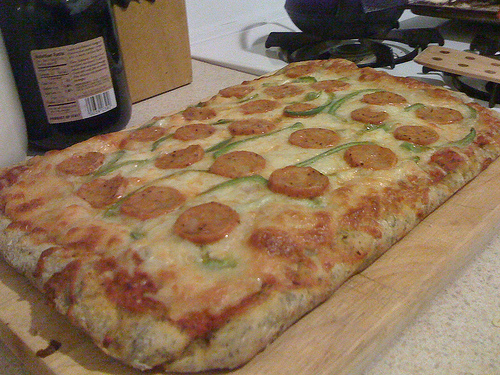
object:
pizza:
[1, 58, 499, 375]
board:
[1, 157, 500, 373]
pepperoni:
[174, 202, 241, 246]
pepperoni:
[266, 164, 332, 199]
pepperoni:
[54, 150, 105, 175]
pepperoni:
[217, 84, 253, 100]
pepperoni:
[414, 105, 464, 124]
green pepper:
[85, 149, 149, 179]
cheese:
[3, 59, 500, 330]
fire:
[278, 35, 415, 65]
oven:
[188, 1, 500, 109]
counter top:
[0, 57, 499, 374]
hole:
[440, 49, 451, 55]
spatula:
[411, 44, 500, 82]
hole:
[431, 56, 444, 62]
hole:
[464, 55, 475, 61]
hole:
[457, 62, 470, 70]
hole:
[491, 61, 500, 67]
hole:
[484, 68, 497, 75]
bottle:
[1, 0, 134, 156]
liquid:
[2, 6, 130, 154]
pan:
[284, 1, 409, 38]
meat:
[411, 100, 465, 129]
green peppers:
[287, 141, 365, 167]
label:
[28, 35, 119, 125]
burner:
[271, 25, 433, 71]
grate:
[262, 27, 445, 70]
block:
[110, 0, 193, 105]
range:
[170, 88, 469, 151]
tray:
[404, 0, 499, 23]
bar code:
[82, 89, 117, 117]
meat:
[117, 182, 186, 221]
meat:
[206, 148, 269, 180]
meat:
[287, 126, 340, 149]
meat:
[228, 114, 275, 137]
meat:
[167, 121, 216, 144]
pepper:
[284, 89, 335, 118]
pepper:
[397, 126, 477, 152]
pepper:
[149, 134, 175, 154]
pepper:
[464, 102, 479, 121]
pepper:
[285, 75, 317, 84]